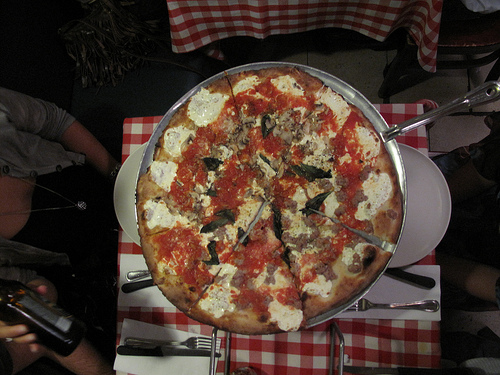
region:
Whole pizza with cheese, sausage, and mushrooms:
[132, 67, 403, 335]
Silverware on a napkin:
[116, 318, 223, 374]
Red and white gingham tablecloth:
[166, 1, 438, 70]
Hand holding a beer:
[0, 278, 82, 358]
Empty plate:
[381, 137, 450, 265]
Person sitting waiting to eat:
[0, 86, 118, 372]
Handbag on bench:
[55, 3, 197, 80]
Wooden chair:
[383, 3, 498, 105]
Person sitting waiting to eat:
[430, 122, 498, 314]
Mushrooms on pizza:
[200, 210, 234, 231]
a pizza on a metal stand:
[130, 67, 427, 334]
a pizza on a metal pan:
[146, 86, 379, 331]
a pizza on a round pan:
[117, 54, 392, 360]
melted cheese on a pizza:
[167, 89, 232, 174]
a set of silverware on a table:
[112, 334, 215, 365]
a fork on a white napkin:
[340, 294, 439, 321]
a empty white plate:
[402, 142, 447, 283]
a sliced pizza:
[147, 68, 387, 325]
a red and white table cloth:
[301, 324, 435, 374]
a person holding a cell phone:
[10, 264, 77, 363]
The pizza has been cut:
[114, 62, 441, 302]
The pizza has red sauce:
[167, 97, 359, 316]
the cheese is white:
[151, 105, 369, 287]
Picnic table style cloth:
[182, 315, 414, 372]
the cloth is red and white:
[232, 316, 412, 371]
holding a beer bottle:
[3, 260, 87, 334]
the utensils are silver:
[115, 329, 216, 366]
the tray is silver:
[122, 56, 419, 321]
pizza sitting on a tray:
[107, 46, 447, 338]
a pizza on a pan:
[112, 61, 489, 354]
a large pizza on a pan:
[112, 41, 482, 355]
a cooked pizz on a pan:
[150, 21, 494, 293]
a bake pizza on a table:
[150, 57, 454, 358]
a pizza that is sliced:
[103, 41, 493, 350]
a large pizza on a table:
[137, 41, 399, 365]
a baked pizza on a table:
[105, 47, 430, 369]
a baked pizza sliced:
[103, 51, 493, 265]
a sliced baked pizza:
[92, 36, 399, 353]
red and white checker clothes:
[89, 40, 464, 367]